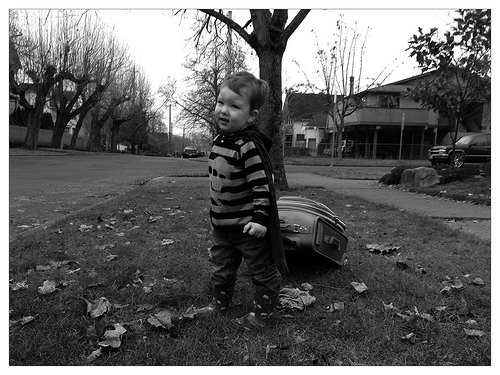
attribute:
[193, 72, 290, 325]
boy — little, light skinned, white, standing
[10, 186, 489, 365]
grass — green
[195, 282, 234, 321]
boot — rubber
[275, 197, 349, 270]
suitcase — big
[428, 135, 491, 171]
suv — parked, black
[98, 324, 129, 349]
leaf — fallen, crumpled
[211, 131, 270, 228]
sweater — stripped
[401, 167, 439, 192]
boulder — large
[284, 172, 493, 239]
sidewalk — empty, suburban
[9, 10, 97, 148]
tree — leafless, dry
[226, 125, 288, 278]
cape — long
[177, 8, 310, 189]
tree — bare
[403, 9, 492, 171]
tree — small